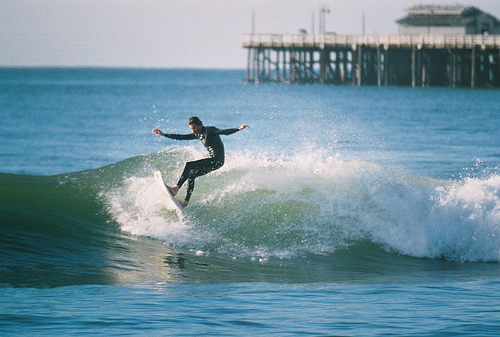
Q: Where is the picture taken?
A: The ocean.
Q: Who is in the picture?
A: A man.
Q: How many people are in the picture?
A: One.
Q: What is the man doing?
A: Surfing.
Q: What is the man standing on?
A: Surfboard.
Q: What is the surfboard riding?
A: Wave.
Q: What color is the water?
A: Blue.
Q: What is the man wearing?
A: Wetsuit.